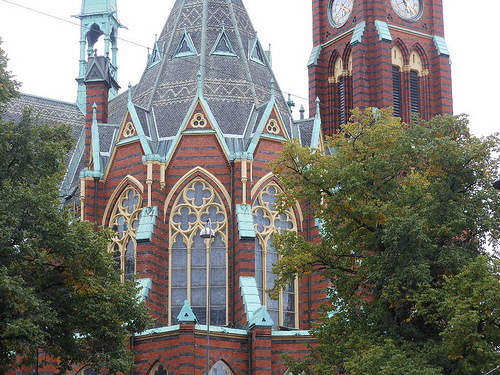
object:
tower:
[306, 0, 454, 150]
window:
[156, 166, 230, 323]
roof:
[60, 85, 326, 195]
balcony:
[138, 307, 251, 338]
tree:
[267, 107, 498, 374]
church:
[49, 1, 351, 375]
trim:
[111, 97, 326, 142]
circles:
[182, 178, 214, 207]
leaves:
[384, 142, 403, 162]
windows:
[251, 170, 303, 332]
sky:
[11, 15, 77, 88]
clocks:
[326, 1, 356, 26]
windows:
[121, 119, 138, 138]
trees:
[262, 106, 497, 374]